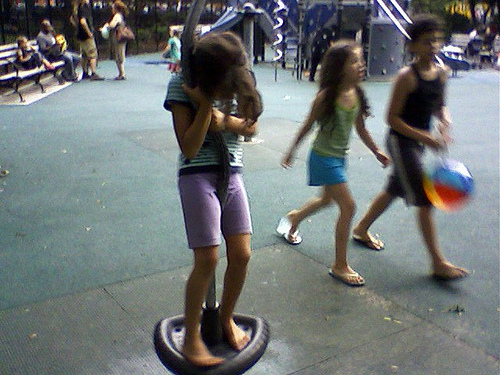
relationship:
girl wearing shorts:
[153, 26, 282, 373] [181, 165, 253, 242]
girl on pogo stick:
[153, 26, 282, 373] [177, 9, 236, 210]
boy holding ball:
[392, 13, 474, 294] [426, 152, 472, 213]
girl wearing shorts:
[295, 30, 368, 265] [306, 142, 348, 189]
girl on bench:
[13, 37, 55, 72] [3, 40, 70, 82]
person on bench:
[30, 20, 79, 71] [3, 40, 70, 82]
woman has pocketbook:
[105, 0, 138, 81] [111, 23, 137, 46]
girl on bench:
[10, 35, 42, 72] [3, 40, 70, 82]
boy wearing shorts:
[392, 13, 474, 294] [388, 121, 443, 203]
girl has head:
[153, 26, 282, 373] [185, 33, 244, 97]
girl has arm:
[153, 26, 282, 373] [171, 100, 210, 157]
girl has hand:
[153, 26, 282, 373] [185, 82, 217, 102]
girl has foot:
[153, 26, 282, 373] [220, 312, 251, 351]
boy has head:
[392, 13, 474, 294] [405, 20, 447, 62]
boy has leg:
[392, 13, 474, 294] [391, 131, 446, 267]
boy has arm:
[392, 13, 474, 294] [396, 66, 416, 131]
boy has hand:
[392, 13, 474, 294] [422, 126, 442, 151]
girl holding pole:
[153, 26, 282, 373] [169, 11, 228, 330]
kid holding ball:
[392, 13, 474, 294] [426, 152, 472, 213]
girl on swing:
[153, 26, 282, 373] [149, 267, 290, 373]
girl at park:
[160, 26, 267, 374] [5, 6, 499, 370]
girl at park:
[282, 38, 389, 287] [5, 6, 499, 370]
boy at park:
[350, 16, 474, 281] [5, 6, 499, 370]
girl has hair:
[153, 26, 282, 373] [192, 35, 260, 90]